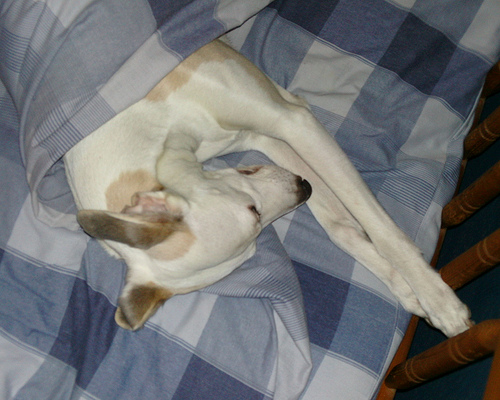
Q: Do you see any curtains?
A: No, there are no curtains.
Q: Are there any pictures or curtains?
A: No, there are no curtains or pictures.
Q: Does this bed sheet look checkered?
A: Yes, the bed sheet is checkered.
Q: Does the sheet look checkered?
A: Yes, the sheet is checkered.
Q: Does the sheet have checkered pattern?
A: Yes, the sheet is checkered.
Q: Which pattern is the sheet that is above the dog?
A: The bed sheet is checkered.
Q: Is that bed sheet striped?
A: No, the bed sheet is checkered.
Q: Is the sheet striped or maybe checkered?
A: The sheet is checkered.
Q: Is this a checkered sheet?
A: Yes, this is a checkered sheet.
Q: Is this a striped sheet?
A: No, this is a checkered sheet.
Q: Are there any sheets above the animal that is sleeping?
A: Yes, there is a sheet above the dog.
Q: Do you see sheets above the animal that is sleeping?
A: Yes, there is a sheet above the dog.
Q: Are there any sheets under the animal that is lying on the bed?
A: No, the sheet is above the dog.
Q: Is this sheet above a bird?
A: No, the sheet is above the dog.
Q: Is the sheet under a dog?
A: No, the sheet is above a dog.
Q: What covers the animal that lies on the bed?
A: The sheet covers the dog.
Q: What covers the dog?
A: The sheet covers the dog.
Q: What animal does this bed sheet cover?
A: The bed sheet covers the dog.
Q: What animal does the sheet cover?
A: The sheet covers the dog.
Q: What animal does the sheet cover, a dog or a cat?
A: The sheet covers a dog.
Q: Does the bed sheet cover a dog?
A: Yes, the bed sheet covers a dog.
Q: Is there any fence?
A: No, there are no fences.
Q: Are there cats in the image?
A: No, there are no cats.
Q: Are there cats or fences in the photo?
A: No, there are no cats or fences.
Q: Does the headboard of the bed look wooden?
A: Yes, the headboard is wooden.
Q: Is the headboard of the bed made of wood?
A: Yes, the headboard is made of wood.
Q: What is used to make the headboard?
A: The headboard is made of wood.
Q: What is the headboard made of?
A: The headboard is made of wood.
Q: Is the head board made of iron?
A: No, the head board is made of wood.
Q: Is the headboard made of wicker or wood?
A: The headboard is made of wood.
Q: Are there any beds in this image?
A: Yes, there is a bed.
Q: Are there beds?
A: Yes, there is a bed.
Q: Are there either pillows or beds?
A: Yes, there is a bed.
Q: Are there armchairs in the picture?
A: No, there are no armchairs.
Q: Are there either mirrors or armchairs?
A: No, there are no armchairs or mirrors.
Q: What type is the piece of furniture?
A: The piece of furniture is a bed.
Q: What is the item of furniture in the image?
A: The piece of furniture is a bed.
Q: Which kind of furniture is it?
A: The piece of furniture is a bed.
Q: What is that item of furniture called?
A: This is a bed.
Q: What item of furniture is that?
A: This is a bed.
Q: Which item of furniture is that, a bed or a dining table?
A: This is a bed.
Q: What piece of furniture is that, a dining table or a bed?
A: This is a bed.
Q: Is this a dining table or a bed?
A: This is a bed.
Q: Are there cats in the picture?
A: No, there are no cats.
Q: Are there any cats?
A: No, there are no cats.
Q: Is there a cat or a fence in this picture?
A: No, there are no cats or fences.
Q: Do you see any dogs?
A: Yes, there is a dog.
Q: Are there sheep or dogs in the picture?
A: Yes, there is a dog.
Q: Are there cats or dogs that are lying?
A: Yes, the dog is lying.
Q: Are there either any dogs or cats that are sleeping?
A: Yes, the dog is sleeping.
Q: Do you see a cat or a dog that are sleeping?
A: Yes, the dog is sleeping.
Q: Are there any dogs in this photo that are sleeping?
A: Yes, there is a dog that is sleeping.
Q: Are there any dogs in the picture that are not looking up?
A: Yes, there is a dog that is sleeping.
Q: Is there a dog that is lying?
A: Yes, there is a dog that is lying.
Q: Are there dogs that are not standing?
A: Yes, there is a dog that is lying.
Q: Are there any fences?
A: No, there are no fences.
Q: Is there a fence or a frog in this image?
A: No, there are no fences or frogs.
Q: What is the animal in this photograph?
A: The animal is a dog.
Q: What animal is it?
A: The animal is a dog.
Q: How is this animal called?
A: This is a dog.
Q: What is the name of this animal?
A: This is a dog.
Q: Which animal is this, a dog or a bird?
A: This is a dog.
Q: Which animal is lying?
A: The animal is a dog.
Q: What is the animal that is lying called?
A: The animal is a dog.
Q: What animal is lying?
A: The animal is a dog.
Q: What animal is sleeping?
A: The animal is a dog.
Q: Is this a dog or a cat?
A: This is a dog.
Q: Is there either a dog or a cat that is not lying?
A: No, there is a dog but it is lying.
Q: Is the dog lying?
A: Yes, the dog is lying.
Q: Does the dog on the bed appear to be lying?
A: Yes, the dog is lying.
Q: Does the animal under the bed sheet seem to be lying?
A: Yes, the dog is lying.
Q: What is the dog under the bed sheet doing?
A: The dog is lying.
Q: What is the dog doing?
A: The dog is lying.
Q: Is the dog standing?
A: No, the dog is lying.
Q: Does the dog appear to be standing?
A: No, the dog is lying.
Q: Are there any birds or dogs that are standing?
A: No, there is a dog but it is lying.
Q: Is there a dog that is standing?
A: No, there is a dog but it is lying.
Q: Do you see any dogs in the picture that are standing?
A: No, there is a dog but it is lying.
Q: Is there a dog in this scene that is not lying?
A: No, there is a dog but it is lying.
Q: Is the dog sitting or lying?
A: The dog is lying.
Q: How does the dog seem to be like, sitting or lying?
A: The dog is lying.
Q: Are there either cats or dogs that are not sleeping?
A: No, there is a dog but it is sleeping.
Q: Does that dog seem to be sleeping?
A: Yes, the dog is sleeping.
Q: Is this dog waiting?
A: No, the dog is sleeping.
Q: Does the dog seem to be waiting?
A: No, the dog is sleeping.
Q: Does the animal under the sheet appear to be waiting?
A: No, the dog is sleeping.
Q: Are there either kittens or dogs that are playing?
A: No, there is a dog but it is sleeping.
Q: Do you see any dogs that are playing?
A: No, there is a dog but it is sleeping.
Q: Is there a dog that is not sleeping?
A: No, there is a dog but it is sleeping.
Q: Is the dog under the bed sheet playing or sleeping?
A: The dog is sleeping.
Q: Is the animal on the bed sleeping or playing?
A: The dog is sleeping.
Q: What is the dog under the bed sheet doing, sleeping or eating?
A: The dog is sleeping.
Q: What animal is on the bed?
A: The dog is on the bed.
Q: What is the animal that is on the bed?
A: The animal is a dog.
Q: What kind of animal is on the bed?
A: The animal is a dog.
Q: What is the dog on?
A: The dog is on the bed.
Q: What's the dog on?
A: The dog is on the bed.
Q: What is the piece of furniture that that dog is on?
A: The piece of furniture is a bed.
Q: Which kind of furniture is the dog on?
A: The dog is on the bed.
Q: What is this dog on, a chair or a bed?
A: The dog is on a bed.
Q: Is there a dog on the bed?
A: Yes, there is a dog on the bed.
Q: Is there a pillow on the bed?
A: No, there is a dog on the bed.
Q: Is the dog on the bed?
A: Yes, the dog is on the bed.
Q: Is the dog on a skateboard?
A: No, the dog is on the bed.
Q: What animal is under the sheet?
A: The dog is under the sheet.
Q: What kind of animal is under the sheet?
A: The animal is a dog.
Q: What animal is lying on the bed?
A: The dog is lying on the bed.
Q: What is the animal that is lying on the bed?
A: The animal is a dog.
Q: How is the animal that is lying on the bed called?
A: The animal is a dog.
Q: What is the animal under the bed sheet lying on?
A: The dog is lying on the bed.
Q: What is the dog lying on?
A: The dog is lying on the bed.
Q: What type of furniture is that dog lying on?
A: The dog is lying on the bed.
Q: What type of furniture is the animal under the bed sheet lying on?
A: The dog is lying on the bed.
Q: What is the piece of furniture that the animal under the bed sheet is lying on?
A: The piece of furniture is a bed.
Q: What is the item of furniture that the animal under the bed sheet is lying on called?
A: The piece of furniture is a bed.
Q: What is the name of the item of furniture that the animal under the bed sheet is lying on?
A: The piece of furniture is a bed.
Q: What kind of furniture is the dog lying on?
A: The dog is lying on the bed.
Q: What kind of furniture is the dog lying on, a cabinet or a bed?
A: The dog is lying on a bed.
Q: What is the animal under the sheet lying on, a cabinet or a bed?
A: The dog is lying on a bed.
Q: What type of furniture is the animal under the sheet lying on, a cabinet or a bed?
A: The dog is lying on a bed.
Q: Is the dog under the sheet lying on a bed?
A: Yes, the dog is lying on a bed.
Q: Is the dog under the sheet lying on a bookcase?
A: No, the dog is lying on a bed.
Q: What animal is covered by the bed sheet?
A: The animal is a dog.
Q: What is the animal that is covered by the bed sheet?
A: The animal is a dog.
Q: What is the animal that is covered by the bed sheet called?
A: The animal is a dog.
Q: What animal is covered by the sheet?
A: The animal is a dog.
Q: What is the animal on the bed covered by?
A: The dog is covered by the sheet.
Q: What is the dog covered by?
A: The dog is covered by the sheet.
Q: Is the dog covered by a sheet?
A: Yes, the dog is covered by a sheet.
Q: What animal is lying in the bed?
A: The animal is a dog.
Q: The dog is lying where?
A: The dog is lying in the bed.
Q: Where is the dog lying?
A: The dog is lying in the bed.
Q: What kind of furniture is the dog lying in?
A: The dog is lying in the bed.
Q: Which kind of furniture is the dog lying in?
A: The dog is lying in the bed.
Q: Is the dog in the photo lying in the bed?
A: Yes, the dog is lying in the bed.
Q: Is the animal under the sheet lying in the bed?
A: Yes, the dog is lying in the bed.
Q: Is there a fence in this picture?
A: No, there are no fences.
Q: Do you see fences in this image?
A: No, there are no fences.